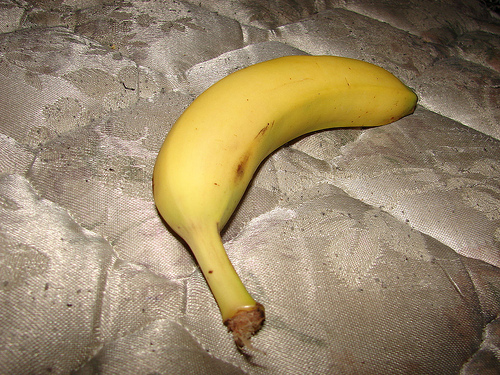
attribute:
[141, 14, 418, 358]
banana — lying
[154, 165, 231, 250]
banana — yellow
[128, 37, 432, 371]
banana — yellow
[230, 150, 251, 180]
dot —  black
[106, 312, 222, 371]
stitching — gray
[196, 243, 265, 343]
stalk — yellow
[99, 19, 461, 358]
banana —  Yellow,  with black dot 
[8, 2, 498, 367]
bed — quilted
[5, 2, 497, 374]
couch — gray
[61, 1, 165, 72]
flower — gray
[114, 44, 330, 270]
banana — yellow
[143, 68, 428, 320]
peel — yellow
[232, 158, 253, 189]
dot — black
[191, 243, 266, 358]
stalk — big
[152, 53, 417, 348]
banana — single, clean,  Yellow, yellow,  with black dot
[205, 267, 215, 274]
dot — black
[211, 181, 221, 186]
dot — black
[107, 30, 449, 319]
banana —  with black dot ,  Yellow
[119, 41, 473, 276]
banana — yellow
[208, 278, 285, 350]
end — brown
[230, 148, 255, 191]
dot — black